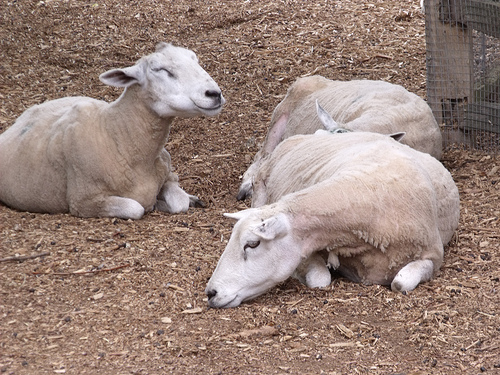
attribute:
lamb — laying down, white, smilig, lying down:
[2, 39, 227, 224]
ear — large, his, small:
[92, 63, 140, 88]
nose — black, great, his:
[204, 87, 219, 99]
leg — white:
[102, 195, 140, 216]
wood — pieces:
[423, 0, 471, 132]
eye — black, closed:
[246, 239, 261, 249]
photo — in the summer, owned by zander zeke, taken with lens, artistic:
[3, 1, 500, 375]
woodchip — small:
[128, 317, 151, 340]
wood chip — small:
[201, 8, 210, 15]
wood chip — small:
[58, 6, 61, 9]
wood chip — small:
[255, 22, 263, 27]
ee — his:
[240, 235, 261, 247]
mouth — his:
[186, 96, 225, 116]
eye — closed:
[153, 64, 176, 78]